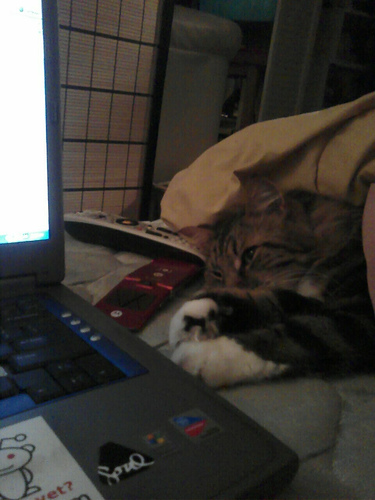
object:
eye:
[240, 244, 257, 264]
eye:
[210, 269, 222, 278]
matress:
[65, 220, 356, 456]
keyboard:
[0, 289, 150, 418]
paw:
[172, 331, 290, 387]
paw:
[168, 286, 255, 350]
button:
[57, 308, 73, 319]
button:
[17, 332, 60, 348]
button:
[1, 346, 15, 359]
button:
[50, 357, 76, 375]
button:
[22, 318, 63, 336]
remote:
[63, 206, 212, 266]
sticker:
[40, 413, 107, 496]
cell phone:
[95, 255, 203, 333]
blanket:
[160, 91, 374, 246]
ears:
[237, 170, 283, 208]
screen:
[5, 4, 51, 244]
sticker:
[167, 405, 223, 444]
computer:
[0, 0, 298, 499]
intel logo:
[173, 412, 194, 432]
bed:
[55, 193, 371, 500]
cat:
[167, 169, 373, 386]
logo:
[5, 411, 75, 497]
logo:
[181, 407, 223, 448]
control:
[50, 190, 205, 275]